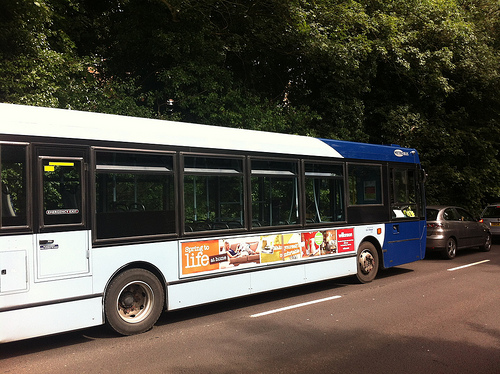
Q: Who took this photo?
A: Someone along the street.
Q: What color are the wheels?
A: Black.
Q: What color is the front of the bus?
A: Blue.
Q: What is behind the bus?
A: Trees.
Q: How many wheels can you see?
A: 4.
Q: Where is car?
A: In front of the bus.